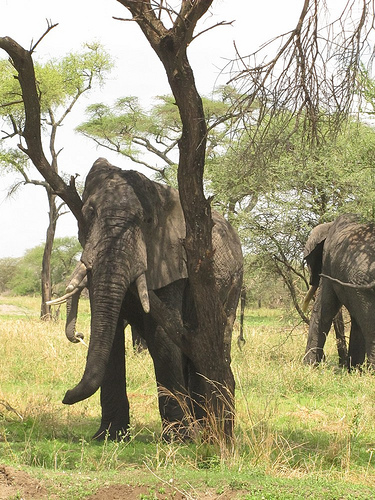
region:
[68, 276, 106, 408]
The trunk of the elephant on the left.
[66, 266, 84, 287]
The left tusk of the elephant on the left.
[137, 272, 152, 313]
The right tusk of the elephant on the left.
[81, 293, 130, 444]
The front left leg of the elephant on the left.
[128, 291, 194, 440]
The front right leg of the elephant on the left.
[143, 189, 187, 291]
The right ear of the elephant on the left.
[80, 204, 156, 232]
The eyes of the elephant on the left.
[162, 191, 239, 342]
The body of the elephant on the left.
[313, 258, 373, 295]
The tail of the elephant on the right.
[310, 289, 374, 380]
The legs of the elephant on the right.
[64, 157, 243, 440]
an elephant relaxing on a tree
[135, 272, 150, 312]
the elephants large ivory tusks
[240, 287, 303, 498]
thick tall grazing grass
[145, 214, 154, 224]
the elephants small dark eyes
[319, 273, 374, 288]
the elephants long skinny tail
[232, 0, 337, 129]
dried up tree branch above the elephants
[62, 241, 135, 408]
the elephants wrinkled trunk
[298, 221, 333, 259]
the elephants floppy ear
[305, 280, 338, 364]
the elephants powerful legs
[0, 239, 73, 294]
thick forest in the distance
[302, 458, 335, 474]
patch of dried grass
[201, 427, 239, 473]
patch of dried grass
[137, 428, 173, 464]
patch of dried grass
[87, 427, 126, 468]
patch of dried grass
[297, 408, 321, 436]
patch of dried grass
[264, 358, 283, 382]
patch of dried grass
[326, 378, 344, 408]
patch of dried grass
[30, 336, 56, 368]
patch of dried grass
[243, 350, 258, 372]
patch of dried grass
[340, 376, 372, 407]
patch of dried grass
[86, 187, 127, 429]
elephant's trunk is wrinkled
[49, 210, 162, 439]
elephant's trunk is wrinkled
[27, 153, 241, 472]
the elephant is gray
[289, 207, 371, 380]
the elephant is gray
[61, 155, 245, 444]
Elephant resting head on tree branch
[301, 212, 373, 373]
Elephant in background facing away from camera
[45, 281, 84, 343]
Tusks and trunk of elephant standing behind elephant in foreground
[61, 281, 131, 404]
Trunk of elephant leaning on tree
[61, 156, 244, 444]
Large gray elephant with very wrinkled skin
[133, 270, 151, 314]
Left tusk of elephant beneath tree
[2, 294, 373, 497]
Grassy field occupied by elephants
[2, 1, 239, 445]
Tree that elephant is resting its head on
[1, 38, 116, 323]
Single tree with green leaves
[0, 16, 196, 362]
Tree branch that elephant is resting its head on